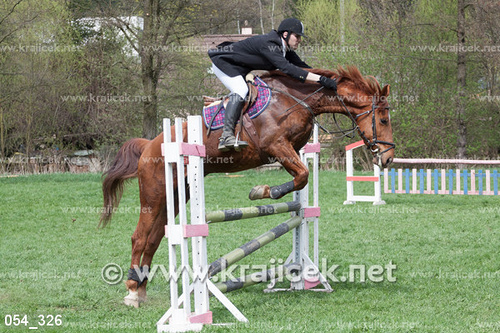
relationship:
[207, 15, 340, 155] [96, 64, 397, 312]
man riding horse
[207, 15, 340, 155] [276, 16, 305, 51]
man wearing cap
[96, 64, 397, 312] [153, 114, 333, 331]
horse jumping over gate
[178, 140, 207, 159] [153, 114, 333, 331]
board on gate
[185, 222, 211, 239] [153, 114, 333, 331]
board on gate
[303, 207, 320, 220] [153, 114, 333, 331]
board on gate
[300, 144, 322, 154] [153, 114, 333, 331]
board on gate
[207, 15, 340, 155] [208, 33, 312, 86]
man wearing jacket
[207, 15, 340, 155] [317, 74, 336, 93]
man wearing glove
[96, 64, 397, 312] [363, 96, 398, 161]
horse wearing a bridle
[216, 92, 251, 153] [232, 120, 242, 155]
boots in stirrup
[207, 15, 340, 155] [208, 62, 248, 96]
man wearing pants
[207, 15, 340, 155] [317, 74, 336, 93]
man wearing a glove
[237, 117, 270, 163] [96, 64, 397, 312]
saddle strap around horse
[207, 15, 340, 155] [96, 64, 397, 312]
jockey on horse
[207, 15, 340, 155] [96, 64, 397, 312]
man on horse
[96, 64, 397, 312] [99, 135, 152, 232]
horse has a tail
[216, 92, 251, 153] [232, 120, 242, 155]
boot in stirrup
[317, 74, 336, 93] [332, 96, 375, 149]
gloved hand holding reign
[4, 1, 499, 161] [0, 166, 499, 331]
trees are behind field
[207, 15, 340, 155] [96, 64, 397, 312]
man riding a horse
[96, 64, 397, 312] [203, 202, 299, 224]
horse jumping over a pole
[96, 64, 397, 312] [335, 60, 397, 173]
horse has a brown head